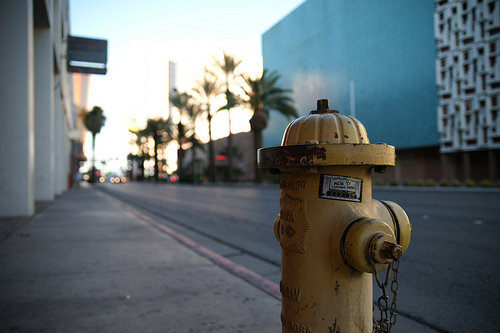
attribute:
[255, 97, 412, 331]
hydrant — yellow, metal, cylindrical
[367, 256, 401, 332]
chain — iron, here, metallic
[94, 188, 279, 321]
curb — brown red, red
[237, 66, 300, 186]
palmtree — growing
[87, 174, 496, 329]
road — here, tarmacked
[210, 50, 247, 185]
palmtree — growing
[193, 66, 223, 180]
palmtree — growing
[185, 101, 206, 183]
palmtree — growing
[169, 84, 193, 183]
palmtree — growing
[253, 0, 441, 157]
wall — blue, here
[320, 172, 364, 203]
sticker — white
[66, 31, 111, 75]
sign — black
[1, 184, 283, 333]
sidewalk — grey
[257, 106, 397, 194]
paint — peeling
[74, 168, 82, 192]
man — blurry, walking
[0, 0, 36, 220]
pillar — white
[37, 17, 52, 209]
pillar — white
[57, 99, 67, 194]
pillar — white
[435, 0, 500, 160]
design — white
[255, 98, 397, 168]
cap — yellow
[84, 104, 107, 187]
palmtree — here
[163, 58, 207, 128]
billboard — here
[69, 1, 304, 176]
sky — here